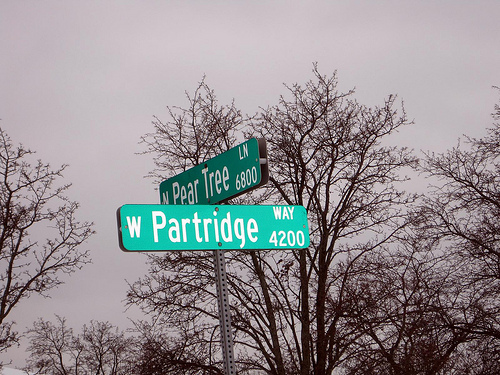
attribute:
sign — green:
[111, 197, 318, 264]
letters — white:
[125, 208, 313, 252]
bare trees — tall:
[143, 57, 484, 352]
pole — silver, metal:
[208, 255, 250, 369]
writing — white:
[149, 210, 259, 247]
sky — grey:
[3, 3, 498, 338]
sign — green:
[116, 203, 311, 250]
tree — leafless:
[0, 100, 98, 373]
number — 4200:
[265, 225, 308, 249]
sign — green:
[192, 210, 319, 252]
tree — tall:
[1, 127, 95, 374]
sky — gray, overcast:
[4, 5, 482, 61]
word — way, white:
[268, 200, 310, 224]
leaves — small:
[341, 101, 437, 152]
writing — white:
[144, 203, 304, 244]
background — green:
[116, 202, 310, 252]